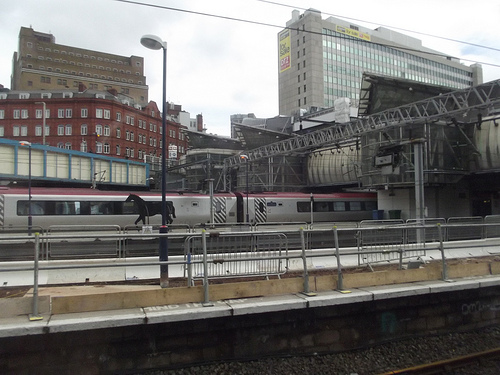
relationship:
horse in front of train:
[126, 193, 176, 227] [1, 186, 378, 235]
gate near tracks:
[186, 234, 287, 277] [4, 218, 500, 259]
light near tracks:
[140, 34, 169, 52] [4, 218, 500, 259]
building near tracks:
[0, 139, 154, 185] [4, 218, 500, 259]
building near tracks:
[1, 88, 189, 177] [4, 218, 500, 259]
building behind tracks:
[0, 139, 154, 185] [4, 218, 500, 259]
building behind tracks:
[1, 88, 189, 177] [4, 218, 500, 259]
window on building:
[82, 106, 88, 117] [1, 88, 189, 177]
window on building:
[66, 107, 73, 118] [0, 139, 154, 185]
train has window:
[1, 186, 378, 235] [19, 201, 136, 213]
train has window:
[1, 186, 378, 235] [298, 202, 370, 209]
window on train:
[19, 201, 136, 213] [1, 186, 378, 235]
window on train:
[298, 202, 370, 209] [1, 186, 378, 235]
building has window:
[1, 88, 189, 177] [82, 106, 88, 117]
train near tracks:
[1, 186, 378, 235] [4, 218, 500, 259]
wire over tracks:
[122, 0, 499, 72] [4, 218, 500, 259]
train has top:
[1, 186, 378, 235] [2, 192, 374, 198]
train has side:
[1, 186, 378, 235] [6, 197, 373, 219]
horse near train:
[126, 193, 176, 227] [1, 186, 378, 235]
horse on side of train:
[126, 193, 176, 227] [1, 186, 378, 235]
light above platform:
[140, 34, 169, 52] [30, 281, 159, 308]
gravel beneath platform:
[145, 326, 499, 374] [30, 281, 159, 308]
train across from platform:
[1, 186, 378, 235] [30, 281, 159, 308]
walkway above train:
[298, 116, 499, 188] [1, 186, 378, 235]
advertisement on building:
[277, 30, 291, 72] [273, 18, 483, 123]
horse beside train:
[126, 193, 176, 227] [1, 186, 378, 235]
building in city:
[0, 139, 154, 185] [109, 59, 343, 355]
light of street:
[140, 34, 169, 52] [116, 152, 328, 284]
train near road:
[1, 186, 378, 235] [127, 186, 297, 373]